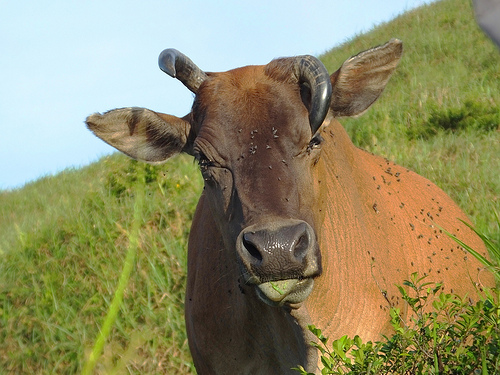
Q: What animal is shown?
A: Cow.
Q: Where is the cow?
A: In a field.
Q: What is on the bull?
A: Flies.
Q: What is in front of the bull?
A: Greenery.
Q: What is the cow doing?
A: Sitting in a field.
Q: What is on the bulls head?
A: Curved horns.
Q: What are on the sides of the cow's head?
A: Brown ears.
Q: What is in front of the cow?
A: Bushes.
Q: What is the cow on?
A: A grassy hill.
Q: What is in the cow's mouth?
A: Its tongue.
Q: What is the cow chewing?
A: Food.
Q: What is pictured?
A: A brown cow.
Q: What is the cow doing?
A: Eating a bush in front of it.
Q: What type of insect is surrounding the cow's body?
A: Insects.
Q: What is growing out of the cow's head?
A: Horns.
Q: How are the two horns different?
A: One horn is growing back into its head.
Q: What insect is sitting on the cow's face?
A: Flies.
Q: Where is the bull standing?
A: On a grassy hill.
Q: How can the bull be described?
A: Brown and covered with flies.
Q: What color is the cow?
A: Brown.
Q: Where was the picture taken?
A: The field.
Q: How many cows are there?
A: One.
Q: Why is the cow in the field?
A: To graze.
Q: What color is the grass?
A: Green.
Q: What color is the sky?
A: Blue.